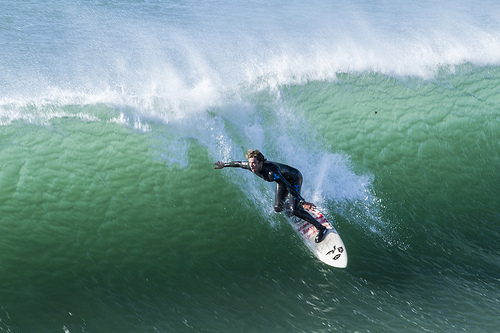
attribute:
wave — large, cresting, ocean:
[0, 47, 488, 329]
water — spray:
[1, 51, 498, 326]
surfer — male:
[201, 149, 308, 224]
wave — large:
[239, 48, 485, 202]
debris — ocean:
[374, 109, 377, 114]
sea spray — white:
[6, 14, 498, 107]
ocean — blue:
[2, 4, 494, 328]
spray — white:
[38, 11, 458, 63]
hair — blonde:
[245, 149, 265, 161]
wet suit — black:
[262, 154, 305, 215]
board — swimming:
[272, 193, 392, 284]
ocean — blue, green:
[214, 100, 484, 237]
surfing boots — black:
[299, 211, 336, 251]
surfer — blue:
[207, 146, 332, 247]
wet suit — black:
[222, 159, 324, 231]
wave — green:
[1, 0, 499, 331]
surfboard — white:
[292, 206, 348, 267]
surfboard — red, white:
[207, 117, 377, 312]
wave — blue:
[78, 89, 429, 277]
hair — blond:
[244, 146, 268, 165]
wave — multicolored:
[346, 43, 498, 177]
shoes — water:
[315, 227, 330, 246]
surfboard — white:
[281, 197, 349, 269]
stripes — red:
[291, 198, 337, 238]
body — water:
[315, 85, 499, 193]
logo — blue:
[268, 168, 282, 183]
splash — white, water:
[187, 42, 377, 102]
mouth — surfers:
[249, 160, 259, 172]